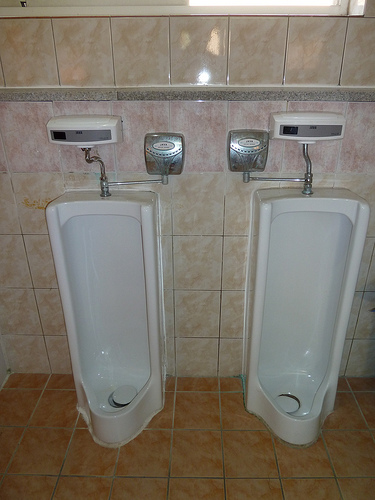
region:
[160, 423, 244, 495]
light orange floor tiles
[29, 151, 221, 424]
the toilet is white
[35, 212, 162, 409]
the toilet is white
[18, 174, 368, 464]
two tall white urinals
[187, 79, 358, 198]
controls for the urinal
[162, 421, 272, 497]
orange brown tile floor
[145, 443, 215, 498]
the grout is dirty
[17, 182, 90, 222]
corrosion on the wall tiles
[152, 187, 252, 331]
white and tan wall tiles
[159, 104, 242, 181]
white and pink wall tiles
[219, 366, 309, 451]
seal around the urinal is corroded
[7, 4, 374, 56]
wooden window frame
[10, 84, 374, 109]
marble ledge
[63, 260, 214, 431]
the toilet is white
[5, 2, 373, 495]
bathroom for men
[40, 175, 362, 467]
toilets are white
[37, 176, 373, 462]
toilets base are in the floor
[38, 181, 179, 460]
toilets are high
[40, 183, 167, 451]
white toilet is clean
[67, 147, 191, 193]
tubes connecting a toilet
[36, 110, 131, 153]
a white box on top a toilet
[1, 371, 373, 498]
tiles of toilet are brown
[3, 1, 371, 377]
bathroom wall has light tan tiles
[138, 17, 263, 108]
tile is shining